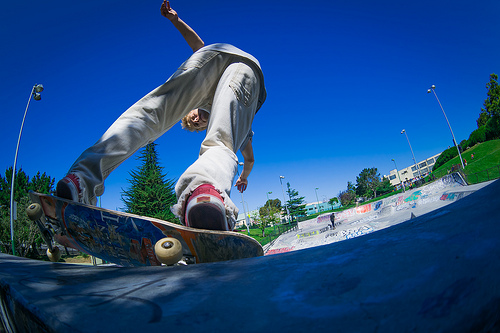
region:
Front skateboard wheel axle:
[26, 195, 63, 270]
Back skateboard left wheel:
[150, 237, 191, 269]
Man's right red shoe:
[175, 180, 237, 228]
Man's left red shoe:
[53, 164, 95, 209]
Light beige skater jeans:
[65, 39, 260, 204]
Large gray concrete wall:
[28, 261, 483, 331]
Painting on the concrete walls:
[339, 193, 434, 226]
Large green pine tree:
[126, 140, 184, 215]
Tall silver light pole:
[6, 74, 42, 239]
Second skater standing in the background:
[328, 210, 338, 232]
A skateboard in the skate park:
[22, 192, 271, 263]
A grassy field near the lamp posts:
[431, 141, 497, 183]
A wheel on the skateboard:
[21, 201, 44, 219]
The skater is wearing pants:
[64, 53, 262, 187]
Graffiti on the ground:
[334, 223, 376, 235]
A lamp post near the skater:
[9, 83, 45, 251]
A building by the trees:
[386, 153, 441, 188]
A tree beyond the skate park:
[354, 168, 391, 201]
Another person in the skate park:
[329, 212, 336, 228]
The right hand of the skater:
[233, 179, 250, 191]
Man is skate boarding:
[26, 1, 265, 263]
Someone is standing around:
[330, 211, 335, 226]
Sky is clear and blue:
[0, 2, 499, 215]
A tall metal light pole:
[427, 83, 464, 169]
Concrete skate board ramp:
[295, 171, 466, 232]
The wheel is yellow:
[153, 236, 181, 260]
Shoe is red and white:
[185, 183, 230, 233]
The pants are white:
[67, 47, 257, 229]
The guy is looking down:
[181, 109, 207, 130]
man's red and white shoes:
[58, 172, 237, 232]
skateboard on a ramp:
[23, 188, 263, 266]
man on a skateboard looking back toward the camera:
[27, 42, 266, 254]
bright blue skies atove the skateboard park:
[271, 4, 482, 80]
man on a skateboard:
[58, 40, 267, 243]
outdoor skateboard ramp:
[228, 180, 458, 317]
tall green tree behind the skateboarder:
[126, 143, 173, 228]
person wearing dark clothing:
[326, 210, 336, 227]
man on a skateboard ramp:
[59, 3, 251, 230]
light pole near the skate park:
[4, 82, 48, 254]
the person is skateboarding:
[30, 9, 273, 264]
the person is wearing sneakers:
[61, 171, 230, 232]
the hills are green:
[446, 135, 496, 182]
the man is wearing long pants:
[58, 50, 259, 212]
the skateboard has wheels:
[28, 191, 260, 275]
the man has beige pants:
[65, 52, 258, 218]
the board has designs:
[33, 198, 260, 268]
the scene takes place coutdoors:
[1, 0, 496, 332]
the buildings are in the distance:
[243, 151, 443, 231]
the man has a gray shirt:
[195, 43, 266, 107]